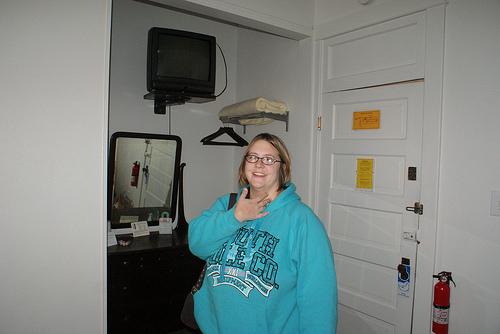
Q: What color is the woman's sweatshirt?
A: Blue.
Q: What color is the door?
A: White.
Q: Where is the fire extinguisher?
A: Next to the door.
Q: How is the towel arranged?
A: It is folded.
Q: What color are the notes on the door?
A: Yellow.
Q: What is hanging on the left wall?
A: A TV.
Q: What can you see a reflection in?
A: The mirror.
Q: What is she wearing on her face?
A: Glasses.